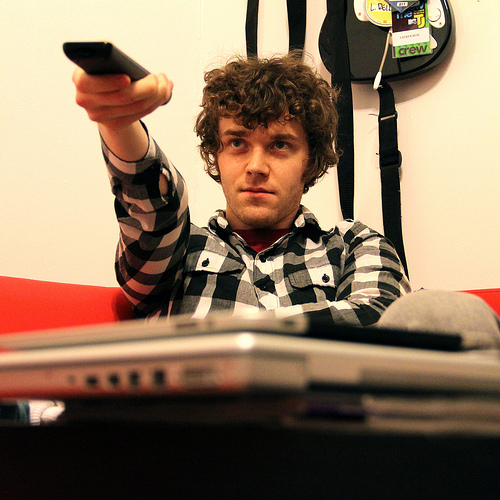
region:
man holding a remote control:
[57, 28, 439, 377]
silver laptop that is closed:
[4, 311, 499, 399]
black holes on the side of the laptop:
[79, 366, 179, 396]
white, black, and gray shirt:
[92, 135, 406, 340]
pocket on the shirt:
[289, 267, 346, 292]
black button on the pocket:
[200, 258, 210, 269]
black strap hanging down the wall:
[314, 9, 437, 289]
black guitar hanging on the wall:
[312, 0, 470, 106]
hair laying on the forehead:
[217, 95, 299, 134]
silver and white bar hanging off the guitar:
[369, 21, 400, 96]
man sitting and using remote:
[70, 50, 411, 317]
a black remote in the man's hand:
[62, 41, 174, 106]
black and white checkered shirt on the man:
[96, 118, 410, 326]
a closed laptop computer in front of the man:
[0, 309, 498, 400]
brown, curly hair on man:
[194, 49, 341, 196]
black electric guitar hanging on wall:
[319, 0, 454, 83]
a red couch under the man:
[0, 270, 498, 332]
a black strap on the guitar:
[325, 0, 407, 280]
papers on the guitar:
[361, 0, 433, 57]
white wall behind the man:
[1, 0, 498, 291]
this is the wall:
[413, 90, 481, 186]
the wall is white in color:
[416, 134, 476, 198]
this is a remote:
[58, 37, 169, 77]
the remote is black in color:
[73, 45, 110, 62]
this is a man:
[77, 38, 422, 325]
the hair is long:
[232, 60, 302, 108]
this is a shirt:
[148, 248, 374, 306]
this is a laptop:
[2, 323, 499, 392]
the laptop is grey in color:
[143, 344, 168, 351]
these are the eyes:
[227, 130, 294, 157]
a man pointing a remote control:
[62, 39, 410, 322]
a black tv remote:
[59, 38, 174, 105]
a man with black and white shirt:
[94, 118, 414, 331]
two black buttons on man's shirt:
[198, 256, 331, 285]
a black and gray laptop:
[0, 312, 498, 437]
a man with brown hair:
[192, 52, 339, 194]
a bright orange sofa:
[0, 274, 499, 336]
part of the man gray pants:
[373, 290, 498, 350]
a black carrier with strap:
[319, 0, 456, 297]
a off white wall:
[0, 1, 499, 288]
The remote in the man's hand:
[63, 35, 171, 105]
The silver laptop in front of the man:
[2, 313, 499, 414]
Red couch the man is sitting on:
[0, 268, 497, 415]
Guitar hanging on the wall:
[316, 0, 455, 88]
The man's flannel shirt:
[97, 124, 412, 329]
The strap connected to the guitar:
[325, 0, 414, 289]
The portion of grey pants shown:
[368, 285, 498, 347]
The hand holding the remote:
[68, 67, 176, 134]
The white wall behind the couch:
[2, 0, 498, 290]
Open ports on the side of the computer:
[77, 364, 179, 389]